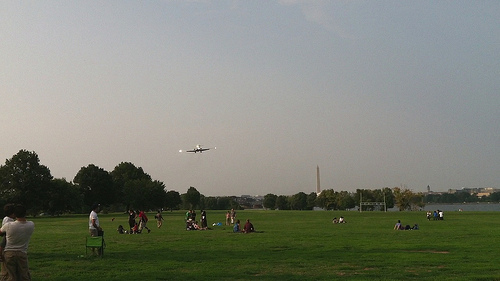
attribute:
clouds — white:
[323, 60, 395, 132]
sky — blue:
[25, 19, 489, 154]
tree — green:
[4, 147, 49, 222]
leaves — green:
[4, 149, 204, 217]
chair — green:
[81, 231, 103, 263]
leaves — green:
[36, 164, 53, 182]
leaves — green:
[55, 186, 77, 213]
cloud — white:
[298, 7, 339, 38]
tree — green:
[15, 124, 230, 216]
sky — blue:
[24, 31, 80, 74]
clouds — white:
[181, 0, 409, 78]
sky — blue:
[1, 1, 497, 197]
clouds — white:
[66, 50, 106, 77]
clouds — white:
[0, 17, 399, 127]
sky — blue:
[0, 5, 482, 144]